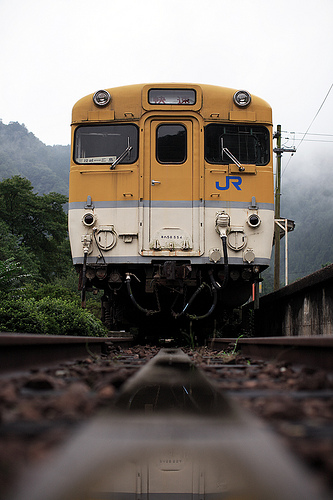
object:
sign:
[215, 175, 243, 192]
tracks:
[0, 323, 333, 499]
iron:
[0, 332, 130, 369]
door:
[146, 118, 198, 253]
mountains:
[0, 117, 68, 203]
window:
[204, 123, 270, 167]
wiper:
[222, 146, 244, 170]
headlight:
[247, 212, 261, 229]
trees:
[0, 174, 42, 242]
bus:
[67, 83, 277, 336]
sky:
[0, 0, 332, 173]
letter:
[215, 176, 242, 190]